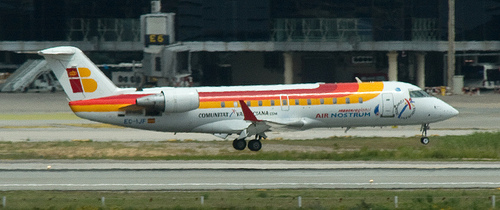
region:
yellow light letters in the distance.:
[140, 30, 170, 47]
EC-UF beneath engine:
[122, 115, 144, 128]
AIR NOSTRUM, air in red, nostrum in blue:
[315, 110, 370, 120]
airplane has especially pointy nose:
[433, 90, 473, 125]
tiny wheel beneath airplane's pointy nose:
[416, 132, 428, 147]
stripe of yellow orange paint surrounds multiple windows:
[67, 71, 383, 117]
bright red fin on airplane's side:
[237, 93, 258, 124]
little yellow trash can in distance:
[435, 81, 447, 96]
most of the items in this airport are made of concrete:
[2, 8, 498, 111]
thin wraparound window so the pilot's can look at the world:
[408, 86, 434, 101]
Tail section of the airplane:
[27, 13, 112, 140]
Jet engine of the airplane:
[128, 84, 210, 117]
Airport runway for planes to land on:
[2, 158, 475, 195]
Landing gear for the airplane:
[220, 120, 448, 155]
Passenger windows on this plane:
[212, 92, 372, 110]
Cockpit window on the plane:
[398, 86, 443, 104]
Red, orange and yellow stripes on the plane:
[67, 78, 385, 111]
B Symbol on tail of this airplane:
[48, 60, 98, 100]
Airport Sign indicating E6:
[129, 27, 174, 56]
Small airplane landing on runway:
[40, 20, 475, 206]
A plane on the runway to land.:
[41, 37, 467, 155]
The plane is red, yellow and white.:
[34, 43, 461, 143]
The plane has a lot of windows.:
[206, 89, 377, 119]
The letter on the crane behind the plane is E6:
[131, 15, 198, 63]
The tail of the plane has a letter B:
[16, 41, 111, 102]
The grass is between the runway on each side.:
[41, 126, 471, 170]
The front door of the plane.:
[373, 88, 419, 125]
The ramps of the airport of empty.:
[243, 20, 485, 86]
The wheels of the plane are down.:
[224, 134, 446, 154]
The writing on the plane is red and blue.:
[313, 95, 390, 121]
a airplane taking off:
[20, 38, 459, 157]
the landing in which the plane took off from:
[58, 166, 430, 178]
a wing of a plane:
[202, 119, 314, 133]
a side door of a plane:
[378, 92, 398, 117]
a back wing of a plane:
[29, 45, 85, 59]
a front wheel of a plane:
[418, 136, 433, 148]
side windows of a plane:
[219, 95, 369, 102]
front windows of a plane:
[406, 90, 432, 100]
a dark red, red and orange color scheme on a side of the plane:
[262, 87, 375, 102]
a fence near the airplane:
[62, 194, 485, 208]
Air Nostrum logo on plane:
[298, 93, 408, 148]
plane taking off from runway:
[20, 25, 468, 191]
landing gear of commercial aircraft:
[210, 109, 455, 176]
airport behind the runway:
[200, 11, 476, 81]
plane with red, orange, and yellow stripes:
[35, 33, 433, 160]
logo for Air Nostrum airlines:
[49, 56, 107, 105]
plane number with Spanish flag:
[117, 113, 163, 129]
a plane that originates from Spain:
[18, 32, 440, 144]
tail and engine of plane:
[45, 34, 182, 141]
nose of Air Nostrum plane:
[340, 64, 469, 144]